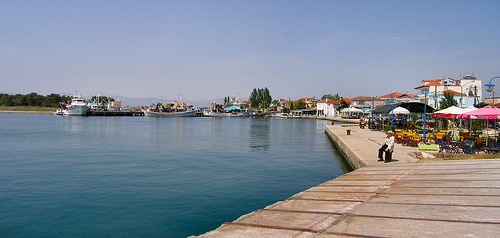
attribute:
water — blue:
[0, 96, 340, 236]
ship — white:
[38, 95, 175, 121]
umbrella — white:
[388, 105, 410, 119]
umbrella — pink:
[460, 104, 498, 116]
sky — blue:
[258, 30, 375, 87]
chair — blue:
[438, 137, 452, 154]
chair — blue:
[457, 137, 474, 153]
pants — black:
[375, 139, 391, 163]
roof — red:
[415, 75, 480, 88]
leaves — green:
[255, 90, 269, 100]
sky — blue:
[2, 3, 498, 95]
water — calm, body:
[0, 106, 355, 228]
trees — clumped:
[17, 93, 46, 101]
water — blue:
[72, 80, 213, 225]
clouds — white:
[18, 56, 193, 90]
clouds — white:
[6, 36, 86, 84]